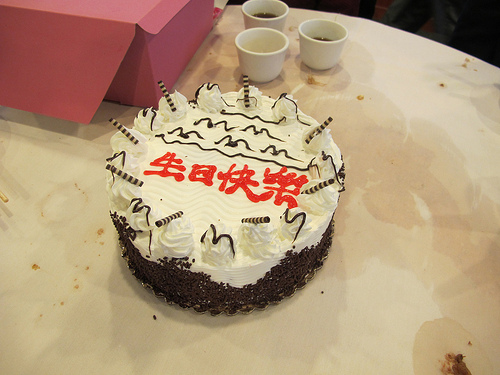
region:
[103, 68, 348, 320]
dark brown and white cake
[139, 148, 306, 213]
red asian writing on a cake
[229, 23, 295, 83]
small white tea cup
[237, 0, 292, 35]
small white tea cup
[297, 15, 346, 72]
small white tea cup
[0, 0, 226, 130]
matte red card board box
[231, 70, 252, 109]
black and white striped biscuit stick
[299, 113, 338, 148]
black and white striped biscuit stick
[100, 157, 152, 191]
black and white striped biscuit stick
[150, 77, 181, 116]
black and white striped biscuit stick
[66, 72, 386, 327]
cake on the table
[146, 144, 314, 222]
red writing on cake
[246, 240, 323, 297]
brown part of cake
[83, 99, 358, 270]
candles on the cake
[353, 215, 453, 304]
white ground under the cake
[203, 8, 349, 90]
cups on the table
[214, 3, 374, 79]
three cups on table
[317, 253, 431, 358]
shadow on the table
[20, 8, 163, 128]
pink box next to cake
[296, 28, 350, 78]
cup with liquid in it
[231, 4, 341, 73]
three small white cups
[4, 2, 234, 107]
pink box on the table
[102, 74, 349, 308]
chocolate cake with white icing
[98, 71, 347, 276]
white icing on cake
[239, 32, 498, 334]
shadows on the white table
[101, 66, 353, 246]
black and white sticks on the cake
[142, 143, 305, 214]
red decorative icingon the top of the cake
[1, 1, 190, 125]
lid of pink box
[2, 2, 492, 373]
white table cake is on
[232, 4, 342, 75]
tiny bowls on the table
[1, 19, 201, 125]
cake on the table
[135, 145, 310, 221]
red frosting on cake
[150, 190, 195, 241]
candle on the cake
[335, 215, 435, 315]
white table in photo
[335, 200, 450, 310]
shadow on the table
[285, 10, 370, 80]
liquid in the photo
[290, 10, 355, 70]
white cup on table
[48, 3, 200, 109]
purple box next to cake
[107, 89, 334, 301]
brown and white cake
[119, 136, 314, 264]
red characters on cake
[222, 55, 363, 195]
black and white candles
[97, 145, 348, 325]
cake on white table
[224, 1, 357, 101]
white cups behind cake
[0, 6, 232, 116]
pink box on table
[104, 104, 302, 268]
white mounds of icing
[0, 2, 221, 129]
pink box is opened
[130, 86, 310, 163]
brown icing on top of cake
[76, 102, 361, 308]
white tablecloth under cake